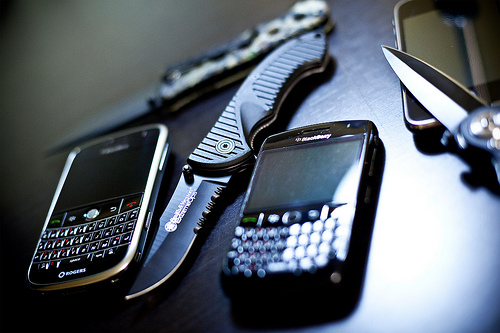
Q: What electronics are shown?
A: Cell phones.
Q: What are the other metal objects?
A: Knives.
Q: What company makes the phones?
A: Blackberry.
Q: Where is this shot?
A: Desk.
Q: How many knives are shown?
A: 3.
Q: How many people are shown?
A: 0.